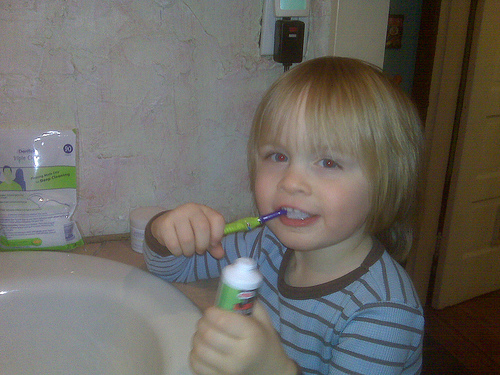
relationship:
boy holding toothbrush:
[142, 55, 426, 375] [208, 210, 308, 238]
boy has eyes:
[142, 55, 426, 375] [257, 134, 355, 182]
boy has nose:
[142, 55, 426, 375] [277, 167, 310, 194]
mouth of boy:
[274, 202, 319, 234] [142, 55, 426, 375]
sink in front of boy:
[0, 234, 246, 371] [142, 55, 426, 375]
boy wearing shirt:
[142, 55, 426, 375] [145, 248, 424, 370]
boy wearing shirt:
[142, 55, 426, 375] [147, 221, 429, 368]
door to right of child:
[425, 0, 499, 315] [142, 54, 427, 374]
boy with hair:
[142, 55, 426, 375] [245, 44, 423, 239]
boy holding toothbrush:
[142, 55, 426, 375] [221, 205, 282, 234]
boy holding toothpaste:
[142, 55, 426, 375] [210, 254, 260, 318]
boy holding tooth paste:
[142, 55, 426, 375] [212, 255, 258, 318]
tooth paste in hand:
[213, 256, 264, 317] [189, 298, 299, 373]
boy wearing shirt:
[142, 55, 426, 375] [141, 209, 425, 375]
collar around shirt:
[256, 224, 396, 297] [155, 226, 425, 373]